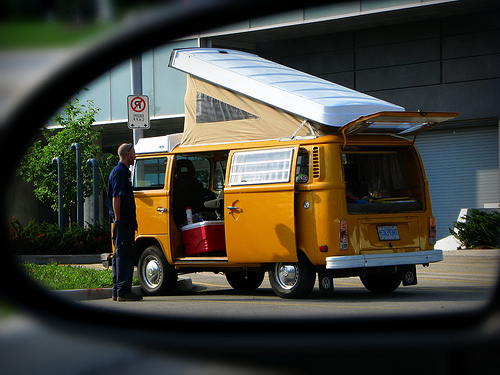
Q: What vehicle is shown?
A: Minivan.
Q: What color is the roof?
A: White.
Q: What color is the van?
A: Orange.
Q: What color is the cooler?
A: Red and white.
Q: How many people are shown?
A: 1.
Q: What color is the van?
A: Yellow.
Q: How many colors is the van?
A: 2.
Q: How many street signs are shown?
A: 1.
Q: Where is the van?
A: Parking lot.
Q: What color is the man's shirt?
A: Blue.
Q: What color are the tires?
A: Black.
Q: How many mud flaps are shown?
A: 2.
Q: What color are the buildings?
A: Grey.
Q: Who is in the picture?
A: A man.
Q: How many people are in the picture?
A: 1.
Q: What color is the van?
A: Yellow.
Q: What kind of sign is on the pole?
A: No parking.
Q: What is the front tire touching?
A: The curb.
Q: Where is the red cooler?
A: In the truck.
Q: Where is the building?
A: Behind the truck.